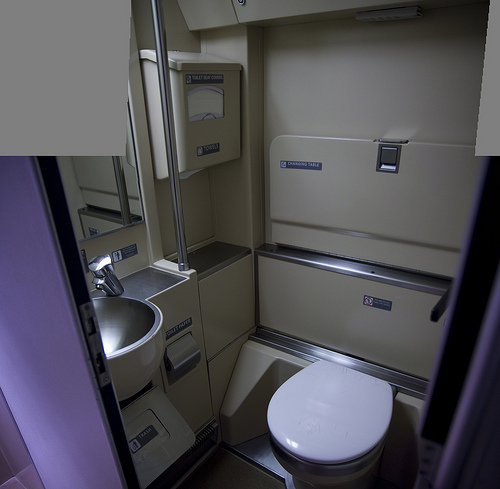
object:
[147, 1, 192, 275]
chromepole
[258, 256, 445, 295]
metal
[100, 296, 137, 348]
metal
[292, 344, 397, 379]
metal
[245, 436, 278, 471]
metal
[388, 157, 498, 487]
walls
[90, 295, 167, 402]
sink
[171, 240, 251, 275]
trashcan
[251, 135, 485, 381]
table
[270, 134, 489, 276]
changing table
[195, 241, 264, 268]
part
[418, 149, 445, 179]
ground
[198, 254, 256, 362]
yellow reflector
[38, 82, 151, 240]
mirror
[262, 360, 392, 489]
toilet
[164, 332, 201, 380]
dispenser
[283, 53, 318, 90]
ground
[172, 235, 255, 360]
trash can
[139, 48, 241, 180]
towel dispenser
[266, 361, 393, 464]
toilet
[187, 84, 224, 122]
paper towel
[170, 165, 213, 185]
napkins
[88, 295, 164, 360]
sink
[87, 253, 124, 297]
faucet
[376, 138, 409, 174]
latch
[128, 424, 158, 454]
sign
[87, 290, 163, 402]
sink bowl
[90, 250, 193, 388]
sink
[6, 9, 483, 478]
bathroom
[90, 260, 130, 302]
metal